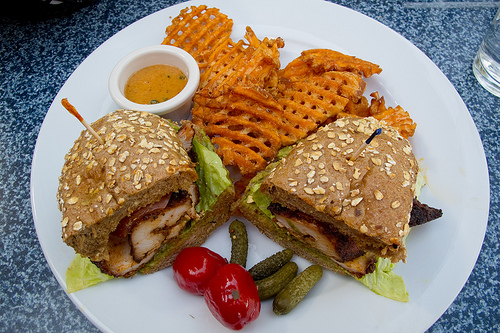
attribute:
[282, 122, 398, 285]
burger — done, brown, ready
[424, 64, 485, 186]
plate — white, glass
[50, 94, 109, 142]
toothpick — orange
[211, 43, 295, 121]
fries — small, done, brown, orange, close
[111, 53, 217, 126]
sauce — yellow, orange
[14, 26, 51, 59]
table — blue, white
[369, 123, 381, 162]
toothpick — black